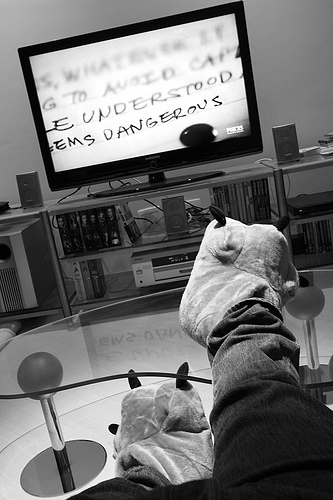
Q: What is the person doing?
A: Relaxing.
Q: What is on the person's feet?
A: House shoes.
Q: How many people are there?
A: One.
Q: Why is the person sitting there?
A: Watching television.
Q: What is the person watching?
A: Television show.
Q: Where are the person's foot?
A: Table.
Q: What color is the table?
A: Clear.